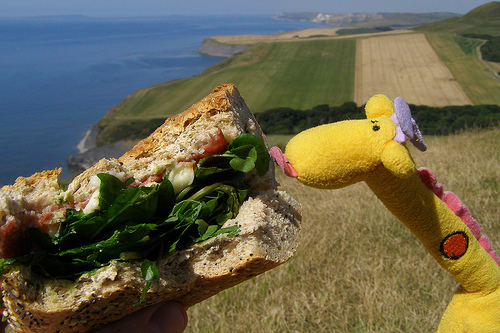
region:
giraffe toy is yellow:
[259, 90, 483, 303]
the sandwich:
[29, 103, 287, 331]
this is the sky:
[93, 0, 125, 15]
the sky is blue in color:
[108, 0, 129, 12]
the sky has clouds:
[16, 0, 48, 17]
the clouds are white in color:
[16, 0, 58, 16]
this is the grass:
[319, 224, 384, 323]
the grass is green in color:
[330, 223, 375, 304]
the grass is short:
[319, 204, 367, 295]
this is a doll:
[283, 95, 498, 328]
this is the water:
[28, 43, 60, 75]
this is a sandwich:
[15, 88, 294, 330]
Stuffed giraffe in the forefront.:
[271, 89, 495, 331]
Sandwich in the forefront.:
[0, 80, 310, 325]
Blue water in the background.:
[0, 0, 329, 185]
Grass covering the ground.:
[186, 123, 496, 331]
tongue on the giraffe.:
[264, 140, 299, 182]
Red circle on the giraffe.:
[437, 229, 474, 258]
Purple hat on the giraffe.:
[375, 93, 427, 155]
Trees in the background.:
[255, 99, 498, 134]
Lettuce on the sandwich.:
[2, 134, 271, 302]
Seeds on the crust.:
[5, 289, 178, 331]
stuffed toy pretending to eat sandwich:
[271, 95, 498, 311]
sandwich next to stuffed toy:
[13, 90, 303, 318]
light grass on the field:
[276, 143, 478, 331]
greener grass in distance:
[259, 48, 352, 99]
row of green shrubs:
[260, 93, 499, 133]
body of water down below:
[3, 9, 85, 152]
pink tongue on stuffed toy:
[268, 145, 293, 180]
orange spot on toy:
[428, 229, 471, 264]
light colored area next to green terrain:
[360, 38, 454, 98]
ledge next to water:
[195, 32, 237, 58]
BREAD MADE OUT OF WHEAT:
[245, 239, 267, 261]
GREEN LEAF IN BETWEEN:
[104, 208, 151, 234]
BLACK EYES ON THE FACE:
[374, 125, 381, 131]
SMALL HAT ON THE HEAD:
[395, 103, 417, 131]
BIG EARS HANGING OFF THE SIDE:
[388, 153, 413, 173]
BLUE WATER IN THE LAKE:
[48, 40, 138, 89]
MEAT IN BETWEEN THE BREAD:
[42, 210, 53, 230]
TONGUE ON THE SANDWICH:
[269, 148, 291, 173]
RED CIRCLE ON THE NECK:
[441, 230, 470, 263]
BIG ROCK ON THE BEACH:
[213, 38, 238, 48]